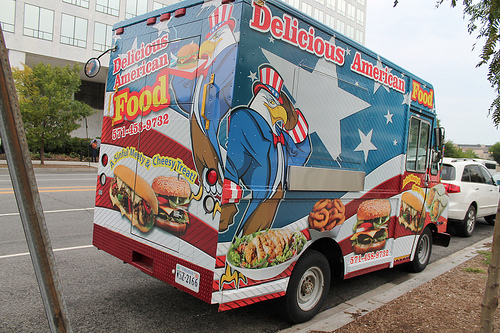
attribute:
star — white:
[350, 124, 379, 168]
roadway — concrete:
[0, 169, 497, 331]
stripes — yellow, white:
[2, 185, 95, 195]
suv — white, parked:
[434, 156, 499, 236]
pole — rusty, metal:
[30, 211, 78, 331]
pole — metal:
[10, 159, 65, 330]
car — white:
[425, 135, 497, 242]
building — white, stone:
[9, 6, 372, 68]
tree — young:
[10, 47, 87, 187]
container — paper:
[308, 222, 342, 238]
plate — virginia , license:
[172, 263, 211, 296]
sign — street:
[237, 10, 467, 106]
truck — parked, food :
[81, 0, 457, 315]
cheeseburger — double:
[353, 216, 391, 245]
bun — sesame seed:
[351, 200, 392, 255]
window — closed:
[285, 59, 379, 205]